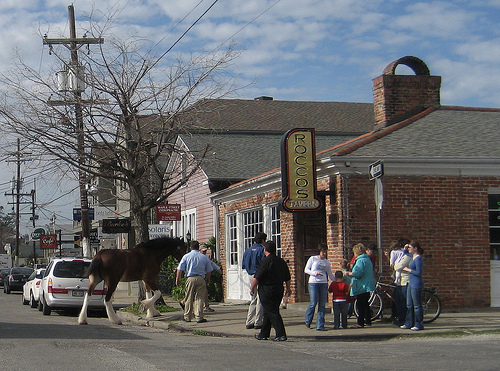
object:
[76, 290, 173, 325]
hooves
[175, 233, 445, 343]
people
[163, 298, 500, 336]
sidewalk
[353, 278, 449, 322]
bike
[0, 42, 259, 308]
tree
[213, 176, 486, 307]
wall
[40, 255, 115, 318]
van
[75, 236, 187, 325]
horse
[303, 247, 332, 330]
woman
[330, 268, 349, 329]
kid